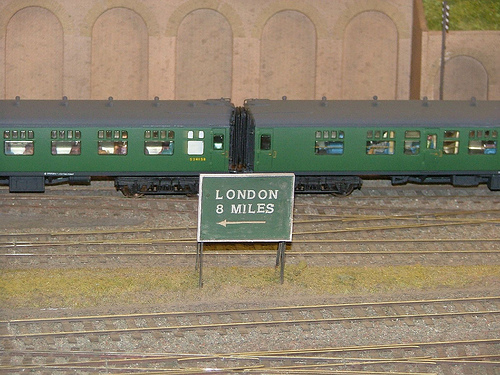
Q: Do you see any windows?
A: Yes, there is a window.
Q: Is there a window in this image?
A: Yes, there is a window.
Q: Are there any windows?
A: Yes, there is a window.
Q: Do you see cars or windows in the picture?
A: Yes, there is a window.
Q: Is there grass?
A: Yes, there is grass.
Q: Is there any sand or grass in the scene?
A: Yes, there is grass.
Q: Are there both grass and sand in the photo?
A: No, there is grass but no sand.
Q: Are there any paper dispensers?
A: No, there are no paper dispensers.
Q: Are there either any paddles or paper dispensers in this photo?
A: No, there are no paper dispensers or paddles.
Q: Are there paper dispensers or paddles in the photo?
A: No, there are no paper dispensers or paddles.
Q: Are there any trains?
A: Yes, there is a train.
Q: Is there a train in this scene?
A: Yes, there is a train.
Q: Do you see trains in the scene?
A: Yes, there is a train.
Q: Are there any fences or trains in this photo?
A: Yes, there is a train.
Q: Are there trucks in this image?
A: No, there are no trucks.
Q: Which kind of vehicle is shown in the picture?
A: The vehicle is a train.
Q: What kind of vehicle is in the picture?
A: The vehicle is a train.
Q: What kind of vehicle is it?
A: The vehicle is a train.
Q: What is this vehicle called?
A: This is a train.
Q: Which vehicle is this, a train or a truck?
A: This is a train.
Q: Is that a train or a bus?
A: That is a train.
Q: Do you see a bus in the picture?
A: No, there are no buses.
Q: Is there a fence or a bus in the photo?
A: No, there are no buses or fences.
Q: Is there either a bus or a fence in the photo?
A: No, there are no buses or fences.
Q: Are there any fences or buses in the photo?
A: No, there are no buses or fences.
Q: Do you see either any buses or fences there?
A: No, there are no buses or fences.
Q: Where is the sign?
A: The sign is on the grass.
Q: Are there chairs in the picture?
A: No, there are no chairs.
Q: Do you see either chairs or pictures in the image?
A: No, there are no chairs or pictures.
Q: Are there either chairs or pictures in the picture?
A: No, there are no chairs or pictures.